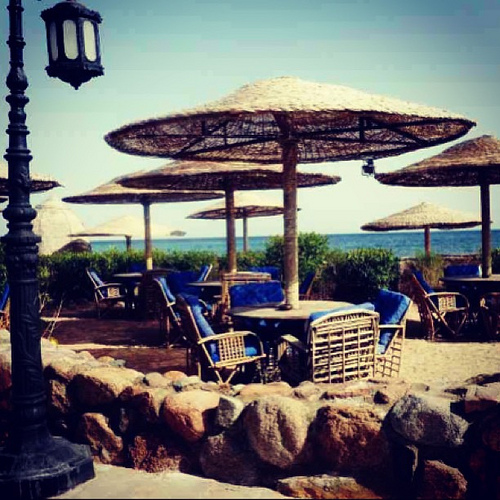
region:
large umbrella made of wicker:
[83, 67, 479, 333]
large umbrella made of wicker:
[372, 128, 498, 287]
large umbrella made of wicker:
[180, 188, 304, 278]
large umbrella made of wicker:
[114, 143, 346, 303]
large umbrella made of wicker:
[57, 165, 223, 295]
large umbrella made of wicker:
[0, 160, 65, 207]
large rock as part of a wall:
[227, 393, 317, 473]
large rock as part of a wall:
[156, 387, 227, 448]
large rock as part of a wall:
[369, 386, 463, 480]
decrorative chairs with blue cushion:
[178, 288, 290, 410]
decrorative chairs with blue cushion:
[394, 268, 490, 333]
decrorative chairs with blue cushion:
[80, 242, 176, 329]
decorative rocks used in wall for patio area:
[87, 335, 473, 499]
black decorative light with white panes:
[34, 0, 133, 92]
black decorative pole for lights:
[1, 41, 108, 485]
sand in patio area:
[417, 328, 496, 398]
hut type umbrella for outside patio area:
[114, 49, 480, 173]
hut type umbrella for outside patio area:
[402, 124, 498, 199]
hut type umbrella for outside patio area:
[54, 147, 292, 280]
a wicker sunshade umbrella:
[102, 78, 474, 163]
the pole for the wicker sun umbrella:
[281, 140, 298, 335]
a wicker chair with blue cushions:
[175, 301, 266, 386]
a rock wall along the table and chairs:
[93, 366, 498, 499]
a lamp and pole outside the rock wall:
[0, 0, 92, 498]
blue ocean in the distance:
[327, 229, 483, 250]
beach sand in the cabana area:
[405, 341, 498, 378]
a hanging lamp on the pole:
[40, 0, 105, 90]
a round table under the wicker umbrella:
[230, 299, 352, 318]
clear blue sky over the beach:
[105, 1, 497, 76]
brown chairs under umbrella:
[152, 230, 412, 405]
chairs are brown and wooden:
[177, 309, 409, 386]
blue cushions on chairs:
[134, 301, 386, 362]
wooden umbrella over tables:
[91, 69, 465, 166]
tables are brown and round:
[243, 253, 365, 338]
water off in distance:
[130, 212, 417, 261]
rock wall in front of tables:
[75, 340, 438, 466]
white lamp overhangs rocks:
[49, 4, 99, 79]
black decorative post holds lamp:
[7, 25, 89, 495]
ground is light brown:
[391, 321, 497, 381]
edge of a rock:
[316, 437, 321, 441]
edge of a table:
[282, 301, 287, 312]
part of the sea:
[341, 228, 351, 238]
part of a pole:
[291, 246, 292, 258]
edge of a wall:
[191, 409, 227, 447]